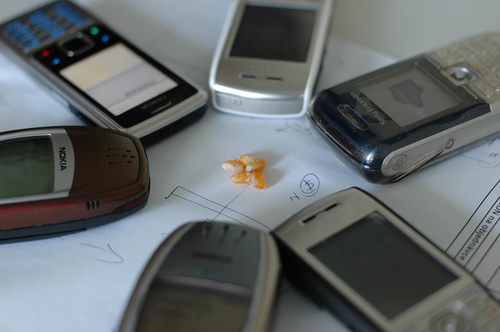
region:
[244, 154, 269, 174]
a yellow kernel of corn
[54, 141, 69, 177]
black writing on the phone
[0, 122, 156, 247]
a red and black cell phone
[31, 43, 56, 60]
a red button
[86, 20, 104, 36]
a green cell phone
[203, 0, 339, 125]
a white and gray cell phone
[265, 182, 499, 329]
a black and gray cell phone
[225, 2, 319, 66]
a dark cell phone screen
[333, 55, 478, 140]
a lit cell phone screen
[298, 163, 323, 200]
a dollar sign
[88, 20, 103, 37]
a green button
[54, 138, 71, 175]
black letters on the phone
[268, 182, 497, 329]
a gray and black cell phone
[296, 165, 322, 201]
a dollar sign on the paper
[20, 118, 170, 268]
red Nokia cell phone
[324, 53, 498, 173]
black and silver cellphone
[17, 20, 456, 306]
six cell phones arranged in a circle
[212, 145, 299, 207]
yellow object in the middle of the phones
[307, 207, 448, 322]
a blank screen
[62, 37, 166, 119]
screen is lit up bright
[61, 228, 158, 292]
right arrow drawn on the paper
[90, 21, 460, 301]
paper under the cell phones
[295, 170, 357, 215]
dollar sign in a circle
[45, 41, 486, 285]
the cell phones are old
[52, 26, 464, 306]
six cell phone in a circle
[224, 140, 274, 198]
yellow kernels on white paper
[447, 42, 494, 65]
number buttons on cell phone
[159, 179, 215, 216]
drawn lines on white paper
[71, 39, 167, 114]
glowing screen on cell phone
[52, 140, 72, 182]
name of company on phone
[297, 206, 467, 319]
blank screen on cell phone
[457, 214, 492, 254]
printed words on paper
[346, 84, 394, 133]
name of cell phone maker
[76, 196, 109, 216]
three holes in phone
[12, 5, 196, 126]
a mobile phone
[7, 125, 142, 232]
nokia mobile phone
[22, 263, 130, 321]
white paper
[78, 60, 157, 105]
phone screen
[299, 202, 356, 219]
mobile ear piece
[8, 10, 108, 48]
mobile phone key pad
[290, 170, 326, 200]
dollar sign on a white paper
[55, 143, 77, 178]
the word nokia on a mobile phone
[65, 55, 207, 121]
a lit mobile phone screen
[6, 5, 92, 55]
a blue lit mobile phone keypad